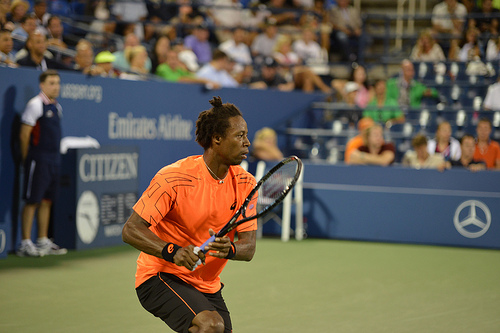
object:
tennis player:
[113, 93, 303, 332]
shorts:
[137, 269, 233, 332]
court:
[4, 220, 499, 332]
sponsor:
[451, 197, 492, 242]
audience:
[0, 0, 499, 168]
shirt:
[132, 146, 258, 296]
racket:
[199, 154, 304, 270]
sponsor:
[105, 110, 193, 151]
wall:
[2, 66, 330, 275]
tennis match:
[3, 97, 499, 331]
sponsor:
[78, 148, 141, 184]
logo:
[55, 82, 101, 101]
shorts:
[23, 157, 64, 202]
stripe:
[25, 162, 39, 197]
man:
[13, 71, 70, 257]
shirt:
[25, 96, 66, 155]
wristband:
[159, 242, 183, 260]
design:
[163, 241, 176, 255]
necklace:
[205, 160, 228, 186]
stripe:
[156, 273, 197, 319]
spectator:
[352, 120, 393, 168]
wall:
[250, 157, 499, 249]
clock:
[99, 192, 140, 237]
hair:
[35, 70, 60, 84]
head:
[198, 99, 250, 166]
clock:
[73, 189, 104, 243]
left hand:
[206, 226, 232, 256]